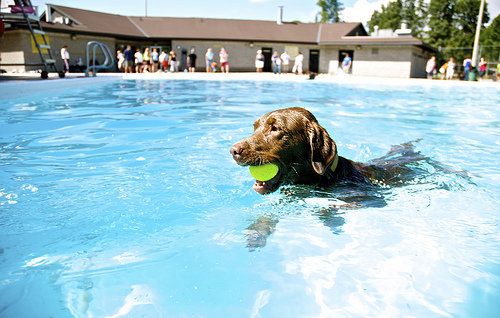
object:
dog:
[228, 106, 467, 252]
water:
[3, 71, 500, 318]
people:
[218, 46, 230, 72]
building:
[0, 0, 443, 76]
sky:
[0, 0, 430, 37]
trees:
[317, 0, 499, 62]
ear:
[307, 119, 339, 170]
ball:
[245, 159, 275, 180]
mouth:
[232, 156, 282, 190]